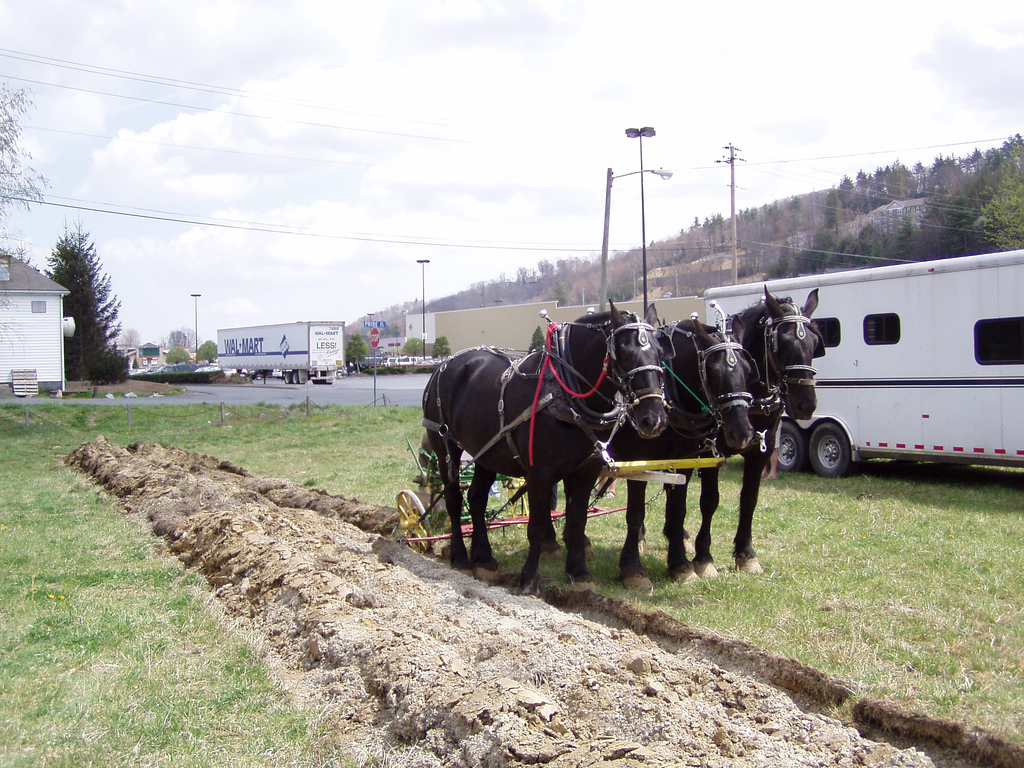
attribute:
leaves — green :
[964, 197, 1022, 235]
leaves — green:
[969, 169, 1017, 215]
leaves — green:
[103, 310, 132, 361]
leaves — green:
[73, 307, 109, 369]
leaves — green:
[54, 241, 122, 327]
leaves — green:
[636, 217, 666, 250]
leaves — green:
[428, 254, 485, 305]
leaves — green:
[447, 242, 505, 299]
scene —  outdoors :
[371, 624, 417, 641]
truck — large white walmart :
[217, 317, 341, 378]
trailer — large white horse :
[708, 242, 1018, 473]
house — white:
[5, 254, 69, 391]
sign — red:
[365, 323, 382, 346]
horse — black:
[433, 305, 664, 584]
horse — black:
[595, 314, 758, 587]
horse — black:
[627, 295, 759, 611]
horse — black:
[717, 278, 838, 579]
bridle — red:
[510, 298, 616, 473]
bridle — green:
[650, 306, 761, 467]